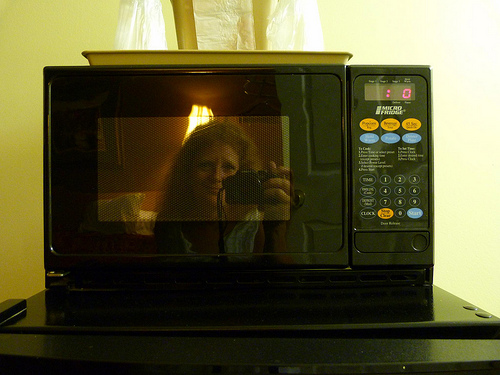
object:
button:
[406, 173, 421, 186]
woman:
[153, 118, 296, 255]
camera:
[221, 166, 285, 205]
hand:
[259, 160, 292, 253]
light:
[183, 104, 214, 144]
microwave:
[42, 63, 435, 289]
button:
[405, 207, 424, 219]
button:
[401, 131, 421, 145]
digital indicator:
[364, 82, 414, 102]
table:
[0, 284, 498, 374]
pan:
[80, 50, 353, 67]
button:
[359, 117, 379, 131]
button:
[379, 117, 401, 131]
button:
[401, 117, 421, 131]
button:
[377, 207, 394, 220]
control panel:
[359, 117, 424, 220]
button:
[357, 131, 379, 144]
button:
[380, 132, 399, 145]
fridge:
[0, 282, 499, 374]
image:
[97, 74, 295, 264]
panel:
[349, 73, 433, 265]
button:
[378, 174, 393, 186]